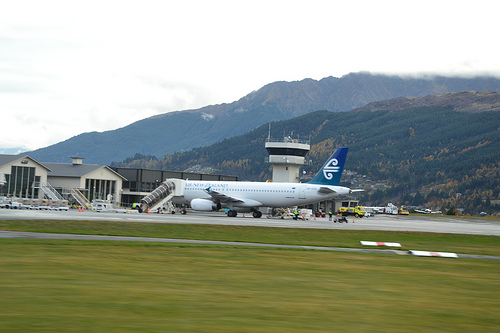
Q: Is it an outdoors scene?
A: Yes, it is outdoors.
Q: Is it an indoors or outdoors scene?
A: It is outdoors.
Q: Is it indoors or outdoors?
A: It is outdoors.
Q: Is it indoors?
A: No, it is outdoors.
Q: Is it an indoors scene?
A: No, it is outdoors.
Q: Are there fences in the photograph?
A: No, there are no fences.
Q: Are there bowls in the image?
A: No, there are no bowls.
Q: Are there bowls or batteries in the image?
A: No, there are no bowls or batteries.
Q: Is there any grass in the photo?
A: Yes, there is grass.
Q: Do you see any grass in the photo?
A: Yes, there is grass.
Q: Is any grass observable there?
A: Yes, there is grass.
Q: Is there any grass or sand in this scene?
A: Yes, there is grass.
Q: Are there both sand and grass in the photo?
A: No, there is grass but no sand.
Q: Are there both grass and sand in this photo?
A: No, there is grass but no sand.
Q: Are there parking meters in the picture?
A: No, there are no parking meters.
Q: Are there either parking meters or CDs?
A: No, there are no parking meters or cds.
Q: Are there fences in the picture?
A: No, there are no fences.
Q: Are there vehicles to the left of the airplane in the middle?
A: Yes, there are vehicles to the left of the plane.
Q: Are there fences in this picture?
A: No, there are no fences.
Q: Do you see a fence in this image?
A: No, there are no fences.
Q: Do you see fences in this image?
A: No, there are no fences.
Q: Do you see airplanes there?
A: Yes, there is an airplane.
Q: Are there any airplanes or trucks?
A: Yes, there is an airplane.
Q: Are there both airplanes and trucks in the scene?
A: Yes, there are both an airplane and a truck.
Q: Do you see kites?
A: No, there are no kites.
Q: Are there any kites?
A: No, there are no kites.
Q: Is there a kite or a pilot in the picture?
A: No, there are no kites or pilots.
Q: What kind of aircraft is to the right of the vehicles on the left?
A: The aircraft is an airplane.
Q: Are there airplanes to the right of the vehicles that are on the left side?
A: Yes, there is an airplane to the right of the vehicles.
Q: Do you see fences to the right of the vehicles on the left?
A: No, there is an airplane to the right of the vehicles.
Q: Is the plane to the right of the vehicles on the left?
A: Yes, the plane is to the right of the vehicles.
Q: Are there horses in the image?
A: No, there are no horses.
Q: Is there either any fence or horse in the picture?
A: No, there are no horses or fences.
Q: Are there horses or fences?
A: No, there are no horses or fences.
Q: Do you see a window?
A: Yes, there are windows.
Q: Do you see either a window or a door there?
A: Yes, there are windows.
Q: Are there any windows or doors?
A: Yes, there are windows.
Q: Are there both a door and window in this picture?
A: No, there are windows but no doors.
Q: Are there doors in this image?
A: No, there are no doors.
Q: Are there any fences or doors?
A: No, there are no doors or fences.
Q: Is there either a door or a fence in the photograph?
A: No, there are no doors or fences.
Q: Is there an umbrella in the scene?
A: No, there are no umbrellas.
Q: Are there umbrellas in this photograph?
A: No, there are no umbrellas.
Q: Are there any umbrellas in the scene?
A: No, there are no umbrellas.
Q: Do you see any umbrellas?
A: No, there are no umbrellas.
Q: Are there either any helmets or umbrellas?
A: No, there are no umbrellas or helmets.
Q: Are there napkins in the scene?
A: No, there are no napkins.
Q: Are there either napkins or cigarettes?
A: No, there are no napkins or cigarettes.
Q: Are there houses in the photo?
A: No, there are no houses.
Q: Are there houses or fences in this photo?
A: No, there are no houses or fences.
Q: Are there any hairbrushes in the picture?
A: No, there are no hairbrushes.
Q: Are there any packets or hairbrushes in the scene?
A: No, there are no hairbrushes or packets.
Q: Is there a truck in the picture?
A: Yes, there is a truck.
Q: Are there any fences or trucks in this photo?
A: Yes, there is a truck.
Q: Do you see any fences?
A: No, there are no fences.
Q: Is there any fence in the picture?
A: No, there are no fences.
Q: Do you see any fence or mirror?
A: No, there are no fences or mirrors.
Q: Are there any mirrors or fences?
A: No, there are no fences or mirrors.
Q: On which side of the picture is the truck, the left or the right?
A: The truck is on the right of the image.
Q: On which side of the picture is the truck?
A: The truck is on the right of the image.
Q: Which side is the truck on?
A: The truck is on the right of the image.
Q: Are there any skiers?
A: No, there are no skiers.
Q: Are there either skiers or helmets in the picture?
A: No, there are no skiers or helmets.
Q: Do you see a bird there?
A: No, there are no birds.